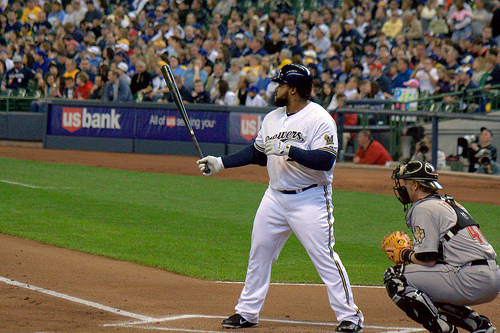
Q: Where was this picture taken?
A: At a baseball field.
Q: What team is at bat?
A: The Brewers.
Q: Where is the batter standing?
A: In the batter's box.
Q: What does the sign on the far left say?
A: Us bank.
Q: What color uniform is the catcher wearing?
A: Gray.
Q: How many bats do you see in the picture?
A: One.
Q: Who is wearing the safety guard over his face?
A: The catcher.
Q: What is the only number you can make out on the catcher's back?
A: 4.